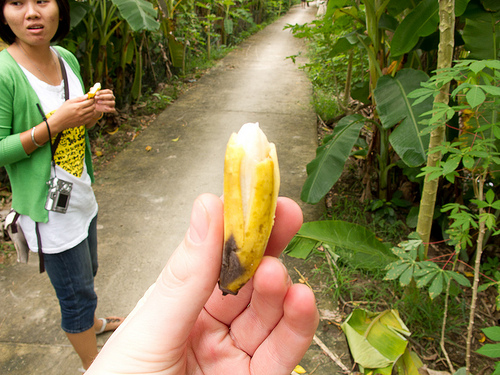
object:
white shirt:
[3, 60, 100, 256]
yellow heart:
[40, 111, 87, 181]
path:
[0, 0, 352, 374]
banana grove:
[0, 1, 498, 374]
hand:
[80, 185, 319, 374]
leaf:
[336, 301, 414, 371]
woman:
[0, 0, 128, 374]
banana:
[83, 79, 104, 100]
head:
[0, 1, 60, 48]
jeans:
[39, 212, 102, 334]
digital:
[39, 115, 75, 214]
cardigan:
[0, 44, 96, 225]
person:
[81, 192, 318, 374]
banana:
[216, 120, 279, 298]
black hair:
[0, 0, 72, 46]